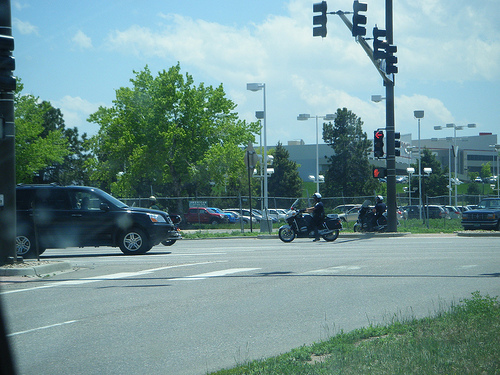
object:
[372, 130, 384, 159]
streetlight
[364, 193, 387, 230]
man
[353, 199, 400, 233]
motorcycle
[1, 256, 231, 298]
line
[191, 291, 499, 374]
grass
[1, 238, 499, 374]
road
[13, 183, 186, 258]
suv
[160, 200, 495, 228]
parking lot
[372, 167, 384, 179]
signal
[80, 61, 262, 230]
tree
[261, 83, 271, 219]
pole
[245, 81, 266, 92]
light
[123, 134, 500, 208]
building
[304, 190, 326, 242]
man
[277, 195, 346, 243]
motorcycle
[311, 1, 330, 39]
streetlight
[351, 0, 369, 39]
streetlight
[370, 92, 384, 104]
light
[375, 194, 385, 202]
helmet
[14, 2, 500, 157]
sky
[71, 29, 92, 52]
cloud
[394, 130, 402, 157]
streetlight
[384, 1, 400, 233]
pole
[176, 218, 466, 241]
grass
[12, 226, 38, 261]
tire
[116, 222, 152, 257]
tire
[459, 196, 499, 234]
truck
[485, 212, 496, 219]
headlight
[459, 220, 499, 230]
fender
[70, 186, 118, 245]
door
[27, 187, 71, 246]
door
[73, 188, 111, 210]
window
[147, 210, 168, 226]
headlight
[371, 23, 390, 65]
streetlight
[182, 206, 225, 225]
cars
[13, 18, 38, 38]
cloud